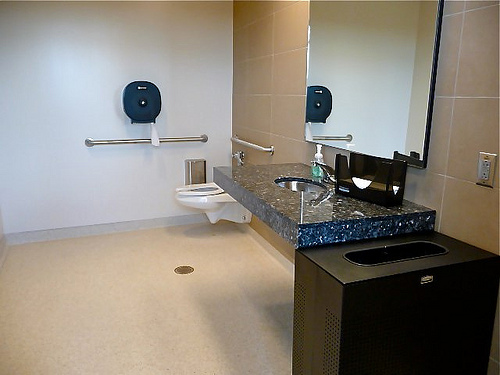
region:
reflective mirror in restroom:
[302, 1, 446, 168]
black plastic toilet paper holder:
[121, 78, 165, 150]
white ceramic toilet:
[174, 182, 256, 226]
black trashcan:
[288, 228, 499, 373]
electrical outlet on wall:
[473, 151, 496, 189]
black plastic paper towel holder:
[333, 150, 405, 206]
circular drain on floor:
[175, 264, 193, 274]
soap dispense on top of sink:
[310, 142, 328, 179]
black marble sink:
[211, 159, 440, 249]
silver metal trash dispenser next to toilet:
[186, 158, 208, 187]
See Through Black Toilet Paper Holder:
[122, 80, 167, 150]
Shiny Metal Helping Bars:
[82, 133, 281, 160]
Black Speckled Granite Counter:
[215, 161, 433, 237]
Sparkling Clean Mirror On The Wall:
[301, 3, 431, 170]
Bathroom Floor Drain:
[164, 261, 203, 280]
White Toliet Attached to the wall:
[172, 151, 259, 234]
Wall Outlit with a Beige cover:
[476, 151, 498, 188]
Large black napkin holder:
[332, 150, 410, 206]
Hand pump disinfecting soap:
[313, 143, 326, 176]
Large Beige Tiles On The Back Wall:
[233, 0, 498, 363]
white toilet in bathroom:
[165, 163, 249, 223]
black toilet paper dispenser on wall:
[128, 75, 161, 121]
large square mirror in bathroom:
[278, 23, 447, 161]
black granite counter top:
[211, 155, 395, 255]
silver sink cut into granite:
[273, 175, 333, 202]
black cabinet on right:
[277, 216, 472, 371]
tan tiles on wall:
[225, 41, 316, 146]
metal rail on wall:
[79, 126, 255, 145]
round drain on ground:
[164, 254, 219, 293]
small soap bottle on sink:
[296, 145, 327, 179]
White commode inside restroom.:
[170, 183, 256, 226]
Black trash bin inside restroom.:
[286, 228, 497, 371]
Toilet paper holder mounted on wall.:
[118, 78, 163, 123]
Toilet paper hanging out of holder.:
[145, 123, 164, 151]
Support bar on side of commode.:
[81, 128, 211, 148]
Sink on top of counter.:
[268, 167, 335, 200]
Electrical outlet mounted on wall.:
[469, 145, 498, 192]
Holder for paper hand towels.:
[328, 149, 415, 211]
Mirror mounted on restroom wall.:
[301, 5, 450, 167]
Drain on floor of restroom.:
[168, 255, 199, 277]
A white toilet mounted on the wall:
[173, 175, 258, 227]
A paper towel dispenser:
[119, 78, 169, 146]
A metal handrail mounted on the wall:
[80, 133, 215, 147]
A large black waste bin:
[286, 223, 498, 372]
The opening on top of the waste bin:
[341, 237, 458, 270]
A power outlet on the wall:
[468, 146, 497, 192]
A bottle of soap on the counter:
[309, 139, 329, 179]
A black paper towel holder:
[330, 149, 409, 209]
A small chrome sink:
[277, 171, 329, 198]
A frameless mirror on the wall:
[299, 0, 451, 170]